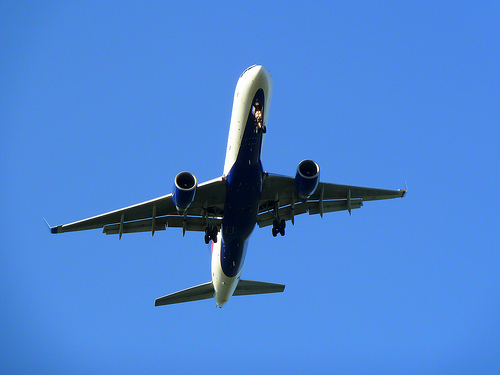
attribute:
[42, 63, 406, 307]
plane — flying, white, commercial, climbing, full, jet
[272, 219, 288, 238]
wheels — black, rear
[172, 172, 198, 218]
engines — cylinders, blue, jet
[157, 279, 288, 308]
tail — flat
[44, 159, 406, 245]
wings — rectangular, light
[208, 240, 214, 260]
stripe — red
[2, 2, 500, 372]
sky — clear, blue, cloudless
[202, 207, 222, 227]
gear — back, landing, rear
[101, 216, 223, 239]
flaps — down